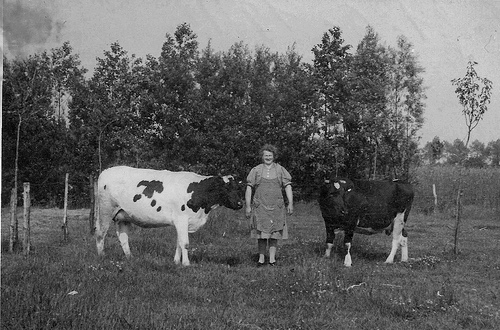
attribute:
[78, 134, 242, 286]
and white cow — black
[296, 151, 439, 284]
black cow — white, standing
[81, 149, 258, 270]
white cow — black, spotted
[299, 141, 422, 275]
black cow — white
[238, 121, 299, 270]
middle aged woman — middle-aged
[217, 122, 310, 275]
picture of a farmer — old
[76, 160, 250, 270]
cow in this photo — white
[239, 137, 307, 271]
lady standing — between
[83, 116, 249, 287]
cow is white — black, spotted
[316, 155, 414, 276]
cow is black — white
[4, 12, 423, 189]
row of trees — standing, behind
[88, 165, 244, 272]
big white cow — black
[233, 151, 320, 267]
woman in dress — standing, between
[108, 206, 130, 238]
udder of the cow — white, black